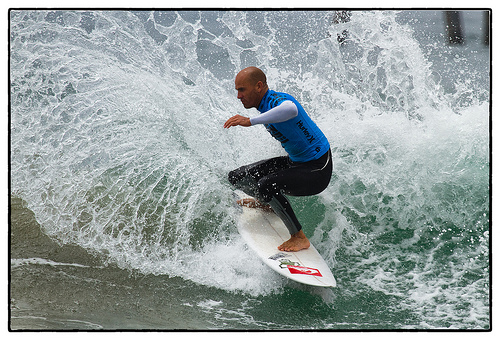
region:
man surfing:
[202, 56, 353, 314]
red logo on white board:
[284, 253, 325, 284]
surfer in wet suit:
[222, 61, 332, 241]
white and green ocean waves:
[62, 175, 114, 232]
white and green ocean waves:
[377, 145, 448, 212]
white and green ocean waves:
[81, 56, 136, 108]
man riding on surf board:
[195, 58, 352, 300]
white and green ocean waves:
[45, 139, 92, 191]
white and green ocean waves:
[130, 212, 197, 259]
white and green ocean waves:
[97, 262, 161, 300]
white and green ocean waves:
[382, 201, 437, 253]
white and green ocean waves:
[377, 68, 428, 112]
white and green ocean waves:
[317, 11, 359, 43]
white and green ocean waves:
[107, 58, 158, 100]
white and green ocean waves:
[52, 55, 92, 105]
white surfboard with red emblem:
[225, 181, 341, 296]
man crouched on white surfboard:
[221, 63, 336, 255]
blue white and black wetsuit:
[225, 89, 338, 236]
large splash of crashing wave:
[9, 11, 489, 300]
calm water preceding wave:
[11, 198, 282, 339]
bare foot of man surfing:
[274, 228, 316, 260]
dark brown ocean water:
[9, 196, 255, 335]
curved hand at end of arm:
[219, 96, 300, 133]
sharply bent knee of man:
[221, 163, 246, 195]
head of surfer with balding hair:
[230, 63, 272, 111]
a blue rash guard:
[252, 95, 334, 165]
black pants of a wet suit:
[225, 151, 333, 237]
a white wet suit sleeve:
[248, 99, 297, 123]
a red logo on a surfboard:
[289, 263, 321, 275]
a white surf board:
[228, 180, 337, 285]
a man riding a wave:
[218, 63, 340, 291]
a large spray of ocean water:
[10, 10, 498, 285]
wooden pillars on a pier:
[439, 11, 491, 44]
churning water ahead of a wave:
[11, 222, 488, 337]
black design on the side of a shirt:
[294, 114, 325, 161]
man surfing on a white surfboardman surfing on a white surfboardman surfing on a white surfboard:
[227, 186, 265, 243]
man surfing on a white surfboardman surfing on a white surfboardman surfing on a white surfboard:
[306, 278, 311, 289]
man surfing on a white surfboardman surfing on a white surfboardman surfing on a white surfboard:
[311, 260, 323, 285]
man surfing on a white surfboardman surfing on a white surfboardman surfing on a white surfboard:
[313, 274, 315, 288]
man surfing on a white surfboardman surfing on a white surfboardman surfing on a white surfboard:
[302, 307, 322, 337]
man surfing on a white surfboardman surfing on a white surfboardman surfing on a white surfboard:
[290, 285, 297, 297]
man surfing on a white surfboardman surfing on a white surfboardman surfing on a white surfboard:
[245, 243, 277, 278]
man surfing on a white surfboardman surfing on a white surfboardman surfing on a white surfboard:
[240, 232, 276, 250]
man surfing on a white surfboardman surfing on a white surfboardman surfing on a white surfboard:
[319, 238, 349, 277]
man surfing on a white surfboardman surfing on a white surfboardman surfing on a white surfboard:
[311, 238, 353, 305]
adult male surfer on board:
[209, 63, 356, 300]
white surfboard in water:
[217, 183, 340, 298]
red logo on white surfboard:
[286, 258, 324, 285]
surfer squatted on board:
[220, 55, 340, 260]